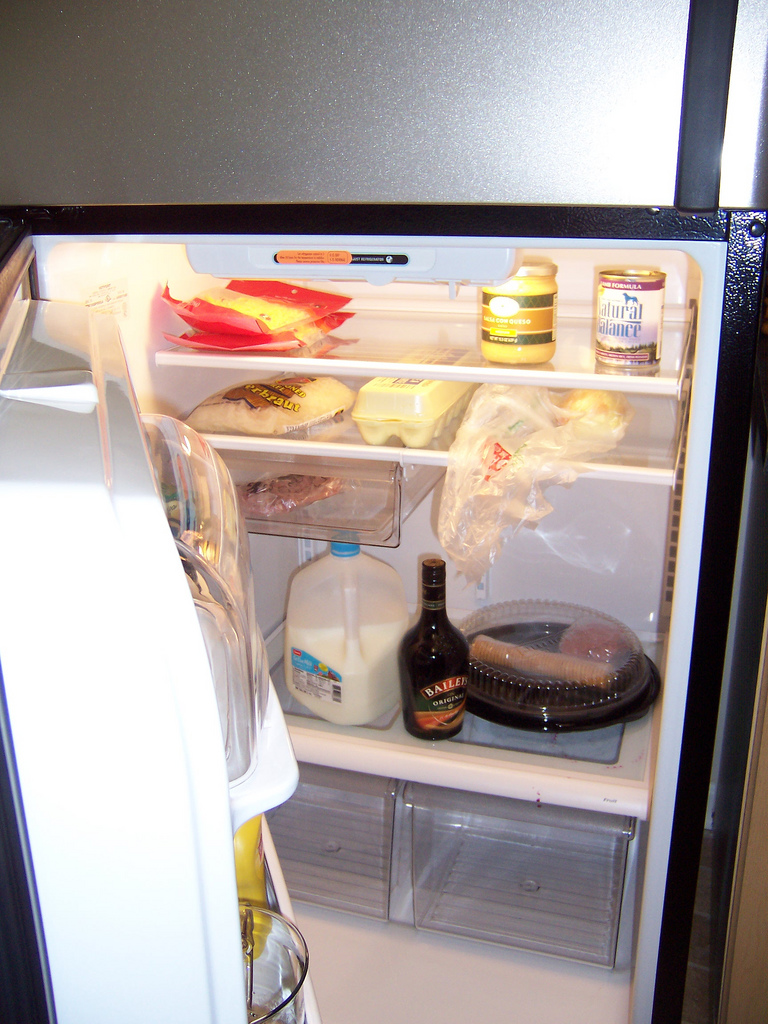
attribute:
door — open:
[8, 21, 763, 1020]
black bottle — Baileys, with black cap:
[400, 552, 472, 739]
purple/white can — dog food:
[595, 266, 664, 366]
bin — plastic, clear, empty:
[380, 787, 643, 988]